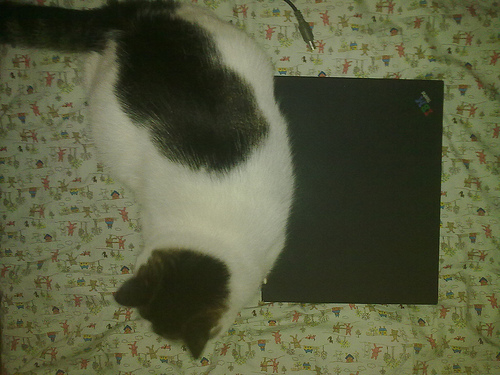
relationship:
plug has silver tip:
[283, 2, 321, 52] [310, 41, 318, 53]